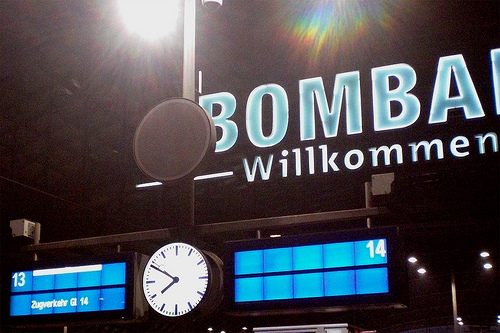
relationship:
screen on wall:
[17, 263, 130, 318] [8, 24, 145, 318]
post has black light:
[162, 186, 209, 235] [128, 96, 210, 206]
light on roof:
[92, 9, 192, 74] [362, 5, 442, 60]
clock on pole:
[138, 242, 218, 319] [164, 4, 201, 331]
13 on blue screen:
[6, 268, 36, 291] [3, 255, 134, 319]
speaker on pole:
[121, 87, 269, 212] [152, 0, 216, 105]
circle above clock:
[130, 97, 217, 185] [141, 239, 211, 317]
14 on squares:
[355, 234, 412, 287] [230, 244, 376, 312]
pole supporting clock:
[175, 17, 196, 108] [138, 232, 224, 318]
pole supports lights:
[161, 183, 200, 238] [232, 237, 392, 302]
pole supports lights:
[161, 183, 200, 238] [10, 261, 129, 314]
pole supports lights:
[22, 203, 380, 224] [232, 237, 392, 302]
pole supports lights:
[22, 203, 380, 224] [10, 261, 129, 314]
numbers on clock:
[145, 244, 204, 314] [141, 239, 211, 317]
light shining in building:
[115, 0, 183, 42] [3, 5, 483, 331]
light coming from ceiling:
[115, 0, 183, 42] [2, 3, 481, 68]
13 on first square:
[6, 268, 36, 291] [7, 270, 36, 292]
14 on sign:
[364, 239, 389, 259] [9, 232, 416, 327]